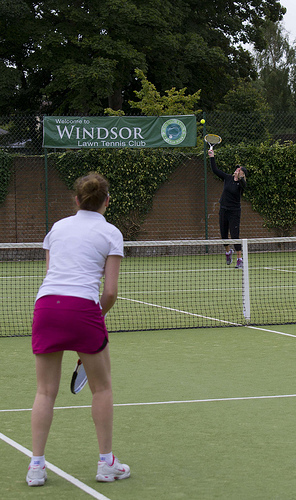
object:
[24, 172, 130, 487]
woman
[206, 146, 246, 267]
woman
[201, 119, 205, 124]
ball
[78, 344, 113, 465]
leg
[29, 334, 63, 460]
leg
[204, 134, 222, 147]
head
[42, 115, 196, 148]
banner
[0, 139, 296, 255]
fence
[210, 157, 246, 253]
black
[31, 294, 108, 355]
skirt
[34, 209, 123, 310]
shirt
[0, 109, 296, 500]
tennis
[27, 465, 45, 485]
shoes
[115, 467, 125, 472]
logo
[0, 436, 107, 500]
lines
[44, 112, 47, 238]
poles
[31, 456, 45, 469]
socks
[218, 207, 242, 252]
pants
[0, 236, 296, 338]
net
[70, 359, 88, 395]
racket